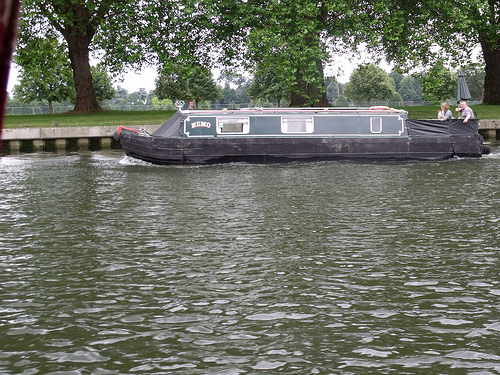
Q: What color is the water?
A: Gray.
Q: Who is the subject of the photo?
A: The boat.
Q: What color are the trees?
A: Green.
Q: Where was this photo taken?
A: In the water.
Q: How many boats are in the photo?
A: One.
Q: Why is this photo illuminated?
A: Sunlight.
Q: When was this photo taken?
A: During the day.